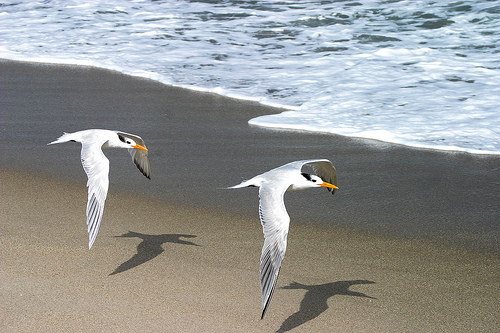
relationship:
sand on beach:
[3, 60, 499, 330] [2, 4, 497, 328]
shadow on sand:
[273, 278, 378, 333] [3, 60, 499, 330]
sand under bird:
[3, 60, 499, 330] [45, 129, 151, 251]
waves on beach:
[2, 4, 496, 158] [2, 4, 497, 328]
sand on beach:
[0, 58, 499, 332] [367, 222, 436, 296]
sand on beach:
[0, 58, 499, 332] [0, 57, 499, 332]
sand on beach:
[0, 58, 499, 332] [372, 256, 457, 313]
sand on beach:
[0, 58, 499, 332] [38, 282, 192, 301]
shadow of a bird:
[273, 278, 378, 333] [53, 110, 159, 146]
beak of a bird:
[319, 181, 339, 193] [217, 154, 340, 320]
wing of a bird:
[293, 145, 351, 191] [246, 137, 349, 292]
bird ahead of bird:
[45, 129, 151, 251] [213, 158, 339, 319]